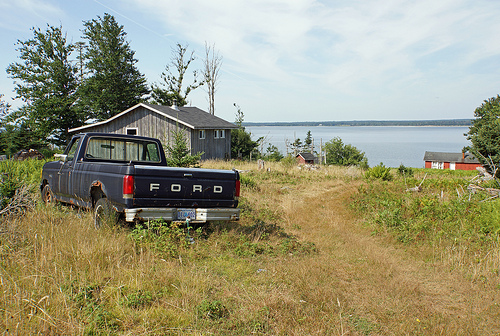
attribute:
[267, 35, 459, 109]
sky — cloudy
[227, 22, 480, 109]
clouds — white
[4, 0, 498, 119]
sky — blue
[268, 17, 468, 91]
sky — blue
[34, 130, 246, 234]
truck — blue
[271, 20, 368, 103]
sky — blue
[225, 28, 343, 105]
clouds — white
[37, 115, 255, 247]
truck — black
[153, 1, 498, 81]
clouds — white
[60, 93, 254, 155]
house — wooden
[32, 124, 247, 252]
blue_truck — black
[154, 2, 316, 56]
cloud — white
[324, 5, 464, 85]
cloud — white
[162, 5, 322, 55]
cloud — white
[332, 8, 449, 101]
cloud — white